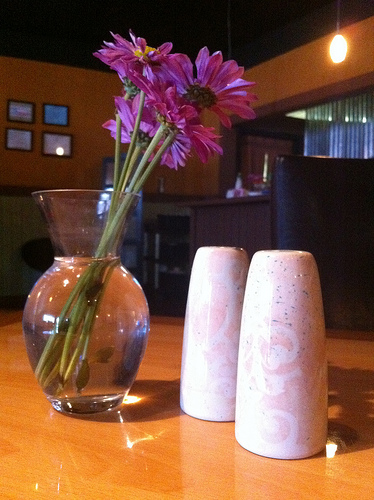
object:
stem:
[32, 89, 176, 394]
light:
[329, 0, 348, 65]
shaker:
[179, 243, 251, 423]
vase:
[22, 188, 150, 417]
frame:
[41, 129, 73, 159]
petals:
[190, 137, 209, 164]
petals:
[212, 104, 234, 129]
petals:
[195, 45, 223, 82]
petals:
[163, 52, 194, 88]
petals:
[218, 98, 256, 121]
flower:
[166, 46, 260, 129]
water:
[22, 282, 149, 409]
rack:
[142, 216, 191, 315]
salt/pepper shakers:
[180, 247, 330, 459]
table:
[0, 308, 374, 500]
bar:
[143, 153, 374, 331]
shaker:
[235, 248, 329, 458]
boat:
[88, 24, 263, 171]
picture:
[42, 101, 70, 126]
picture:
[42, 128, 73, 158]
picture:
[6, 99, 35, 124]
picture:
[4, 125, 34, 152]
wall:
[0, 56, 208, 202]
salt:
[180, 246, 249, 422]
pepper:
[234, 245, 328, 460]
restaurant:
[0, 0, 374, 500]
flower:
[95, 28, 174, 99]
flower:
[103, 92, 166, 164]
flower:
[145, 86, 226, 162]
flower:
[150, 110, 194, 171]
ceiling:
[0, 0, 374, 91]